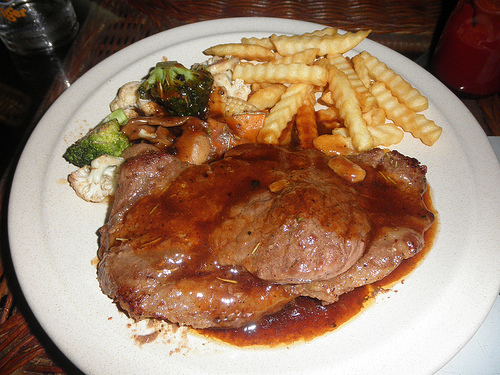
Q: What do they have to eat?
A: Steak, fries and broccoli.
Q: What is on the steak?
A: Gravy.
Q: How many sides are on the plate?
A: Two.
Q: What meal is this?
A: Dinner.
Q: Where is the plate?
A: On the table.